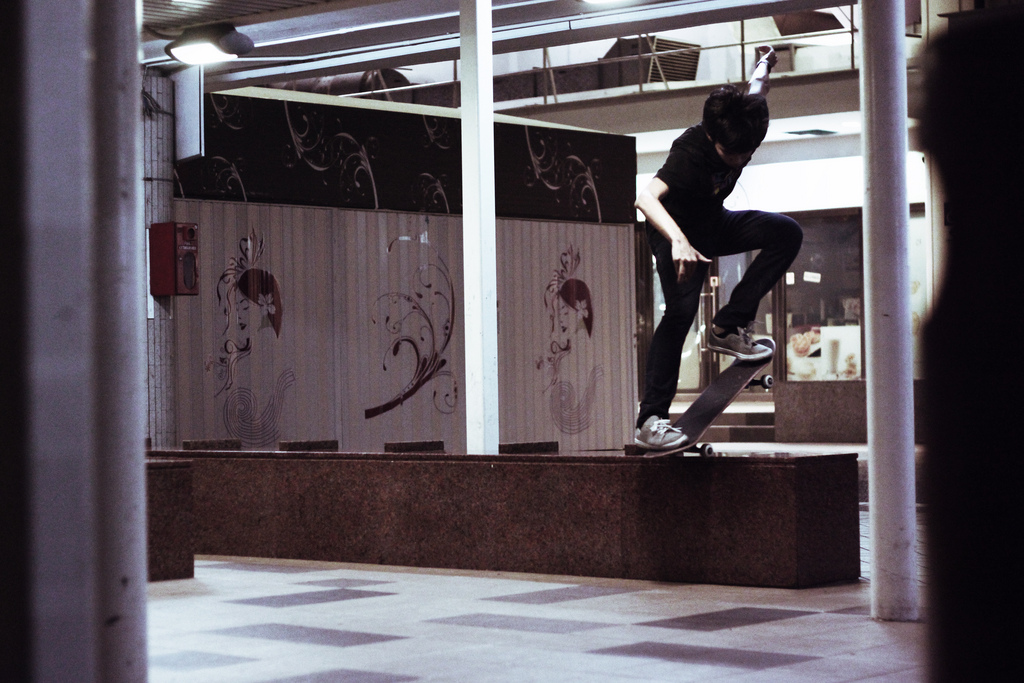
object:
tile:
[424, 613, 626, 634]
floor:
[143, 441, 926, 683]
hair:
[703, 85, 771, 151]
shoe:
[633, 415, 687, 449]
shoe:
[707, 320, 773, 360]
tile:
[632, 607, 824, 632]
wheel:
[699, 443, 713, 457]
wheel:
[761, 374, 774, 389]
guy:
[633, 44, 802, 450]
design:
[203, 228, 294, 449]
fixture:
[143, 450, 859, 589]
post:
[458, 0, 497, 456]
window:
[786, 215, 862, 381]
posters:
[786, 325, 862, 382]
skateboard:
[643, 338, 777, 458]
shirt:
[644, 94, 767, 244]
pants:
[635, 210, 804, 431]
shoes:
[633, 320, 772, 449]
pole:
[859, 0, 920, 621]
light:
[162, 22, 255, 65]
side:
[143, 0, 175, 451]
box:
[150, 221, 199, 296]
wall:
[173, 92, 636, 452]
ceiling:
[140, 0, 1024, 94]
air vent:
[599, 35, 701, 90]